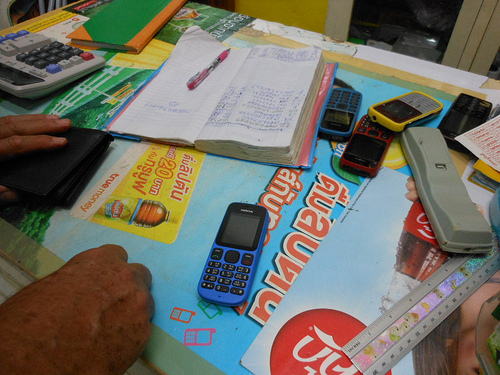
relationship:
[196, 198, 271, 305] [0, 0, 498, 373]
phone on table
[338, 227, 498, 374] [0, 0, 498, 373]
ruler on table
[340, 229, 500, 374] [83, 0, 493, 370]
ruler lying on top of desk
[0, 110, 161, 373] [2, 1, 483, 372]
person sitting at desk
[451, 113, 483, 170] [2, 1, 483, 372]
paper lying on top of desk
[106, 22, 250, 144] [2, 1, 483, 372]
paper lying on top of desk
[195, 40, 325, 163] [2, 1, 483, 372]
paper lying on top of desk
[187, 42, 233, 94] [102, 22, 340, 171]
pen lying on top of book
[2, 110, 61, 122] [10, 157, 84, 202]
finger placed on top of wallet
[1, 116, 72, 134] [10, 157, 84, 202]
finger placed on top of wallet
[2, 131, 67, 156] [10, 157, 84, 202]
finger placed on top of wallet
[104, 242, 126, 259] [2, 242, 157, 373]
finger curled under hand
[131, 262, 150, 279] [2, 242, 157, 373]
finger curled under hand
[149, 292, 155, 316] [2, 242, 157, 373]
finger curled under hand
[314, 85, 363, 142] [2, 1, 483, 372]
cell phone lying on top of desk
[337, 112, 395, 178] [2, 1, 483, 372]
cell phone lying on top of desk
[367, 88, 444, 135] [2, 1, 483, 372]
cell phone lying on top of desk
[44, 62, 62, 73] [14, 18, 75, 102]
button built into calculator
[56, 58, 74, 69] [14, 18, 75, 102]
button built into calculator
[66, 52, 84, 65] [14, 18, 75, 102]
button built into calculator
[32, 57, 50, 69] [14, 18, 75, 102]
button built into calculator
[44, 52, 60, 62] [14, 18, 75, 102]
button built into calculator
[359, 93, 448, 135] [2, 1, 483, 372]
yellow cellphone lying on top of desk